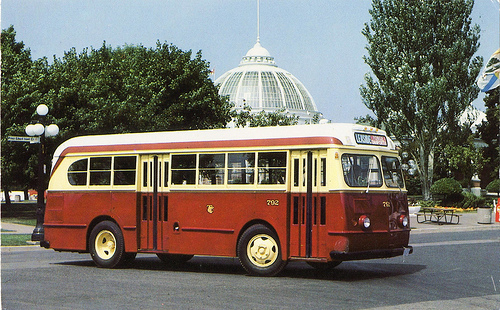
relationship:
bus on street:
[40, 123, 409, 276] [0, 226, 498, 309]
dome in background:
[212, 4, 332, 124] [1, 1, 500, 124]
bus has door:
[40, 123, 409, 276] [138, 152, 167, 252]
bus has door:
[40, 123, 409, 276] [289, 148, 327, 260]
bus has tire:
[40, 123, 409, 276] [87, 220, 136, 269]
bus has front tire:
[40, 123, 409, 276] [236, 224, 290, 278]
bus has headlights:
[40, 123, 409, 276] [356, 213, 411, 229]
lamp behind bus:
[22, 103, 59, 242] [40, 123, 409, 276]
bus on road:
[40, 123, 409, 276] [0, 226, 498, 309]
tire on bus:
[87, 220, 136, 269] [40, 123, 409, 276]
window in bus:
[342, 154, 384, 189] [40, 123, 409, 276]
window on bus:
[171, 155, 286, 186] [40, 123, 409, 276]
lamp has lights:
[22, 103, 59, 242] [24, 103, 59, 137]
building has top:
[212, 4, 332, 124] [240, 1, 279, 67]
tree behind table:
[355, 1, 483, 207] [415, 205, 459, 225]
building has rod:
[212, 4, 332, 124] [254, 1, 260, 44]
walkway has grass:
[1, 201, 44, 245] [3, 232, 41, 245]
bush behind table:
[431, 177, 465, 208] [415, 205, 459, 225]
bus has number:
[40, 123, 409, 276] [266, 200, 281, 207]